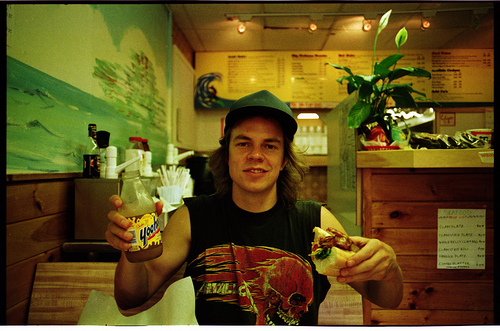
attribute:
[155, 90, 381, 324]
man — smiling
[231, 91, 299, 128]
hat — green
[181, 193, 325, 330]
shirt — black, red, sleeveless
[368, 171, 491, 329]
wall — wood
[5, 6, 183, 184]
wall — painted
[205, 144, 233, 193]
man's hair — long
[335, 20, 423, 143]
plant — green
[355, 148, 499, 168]
counter — white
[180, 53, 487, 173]
wall — white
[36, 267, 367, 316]
bench — wood